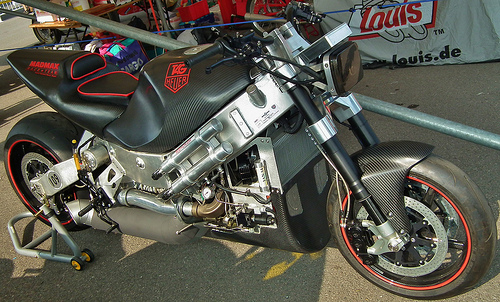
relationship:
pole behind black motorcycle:
[13, 0, 499, 145] [0, 0, 497, 302]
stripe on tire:
[338, 172, 472, 291] [323, 138, 499, 296]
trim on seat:
[68, 51, 137, 97] [7, 47, 138, 137]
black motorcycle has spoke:
[0, 0, 497, 302] [285, 77, 397, 240]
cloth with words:
[306, 5, 497, 71] [355, 5, 423, 29]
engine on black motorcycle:
[141, 81, 307, 238] [0, 0, 497, 302]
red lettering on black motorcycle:
[163, 61, 193, 93] [0, 7, 498, 297]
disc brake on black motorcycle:
[342, 191, 451, 280] [0, 0, 497, 302]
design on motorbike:
[158, 57, 194, 98] [18, 30, 498, 275]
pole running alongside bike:
[13, 0, 499, 145] [23, 20, 498, 273]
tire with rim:
[4, 111, 88, 233] [352, 199, 449, 271]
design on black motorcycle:
[164, 62, 192, 94] [0, 0, 497, 302]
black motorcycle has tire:
[0, 0, 497, 302] [324, 152, 499, 302]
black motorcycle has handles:
[0, 0, 497, 302] [182, 11, 331, 72]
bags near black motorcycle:
[66, 33, 138, 60] [0, 0, 497, 302]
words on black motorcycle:
[21, 53, 61, 76] [0, 0, 497, 302]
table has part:
[22, 3, 122, 48] [82, 9, 107, 36]